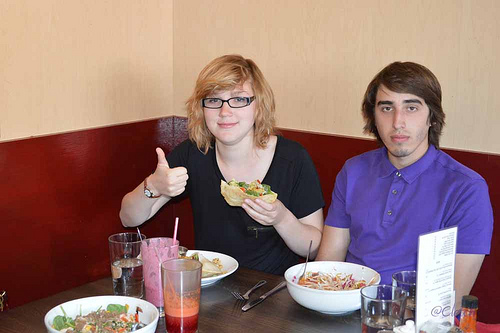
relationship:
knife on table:
[240, 281, 286, 317] [1, 269, 373, 330]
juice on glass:
[162, 298, 198, 321] [155, 253, 204, 331]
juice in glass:
[163, 310, 199, 333] [157, 260, 210, 330]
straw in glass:
[168, 210, 185, 236] [138, 225, 165, 295]